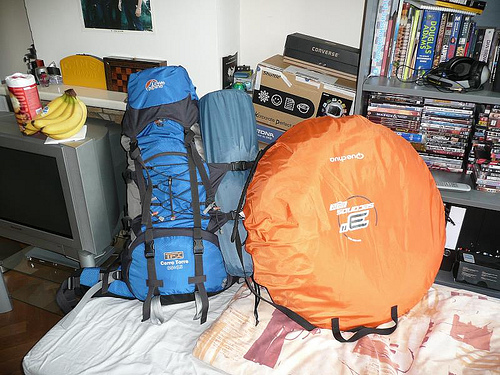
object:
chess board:
[103, 63, 140, 93]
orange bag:
[236, 110, 458, 344]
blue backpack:
[52, 65, 235, 331]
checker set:
[101, 54, 165, 93]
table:
[0, 238, 134, 319]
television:
[0, 110, 133, 270]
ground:
[0, 269, 68, 374]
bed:
[19, 274, 499, 374]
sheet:
[19, 280, 251, 375]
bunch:
[18, 88, 89, 142]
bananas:
[39, 96, 86, 139]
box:
[244, 53, 357, 152]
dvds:
[420, 96, 478, 112]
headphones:
[391, 55, 494, 95]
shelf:
[362, 73, 499, 107]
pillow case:
[190, 279, 498, 374]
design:
[186, 278, 499, 374]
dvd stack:
[413, 97, 475, 174]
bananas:
[28, 97, 75, 130]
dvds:
[422, 104, 477, 117]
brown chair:
[56, 53, 110, 90]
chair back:
[57, 51, 109, 90]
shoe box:
[282, 30, 362, 79]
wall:
[23, 1, 366, 103]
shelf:
[424, 167, 498, 214]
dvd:
[366, 106, 419, 118]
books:
[367, 0, 391, 79]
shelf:
[431, 268, 499, 302]